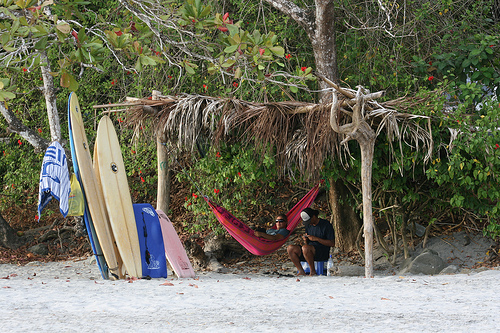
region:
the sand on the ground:
[0, 230, 499, 330]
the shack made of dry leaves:
[91, 73, 461, 277]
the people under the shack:
[252, 207, 336, 274]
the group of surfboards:
[67, 90, 143, 279]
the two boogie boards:
[131, 203, 195, 278]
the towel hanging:
[38, 141, 69, 216]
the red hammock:
[201, 176, 323, 256]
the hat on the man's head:
[300, 206, 316, 223]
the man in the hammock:
[251, 212, 289, 242]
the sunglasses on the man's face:
[274, 217, 285, 224]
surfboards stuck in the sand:
[60, 84, 144, 287]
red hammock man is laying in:
[191, 179, 322, 264]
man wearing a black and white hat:
[285, 208, 332, 273]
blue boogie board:
[135, 202, 168, 277]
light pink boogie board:
[157, 205, 196, 279]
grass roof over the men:
[111, 77, 417, 179]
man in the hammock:
[247, 211, 287, 241]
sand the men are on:
[5, 254, 493, 331]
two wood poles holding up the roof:
[140, 116, 382, 281]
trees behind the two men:
[2, 4, 496, 236]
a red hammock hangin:
[178, 81, 465, 330]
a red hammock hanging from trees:
[172, 135, 379, 282]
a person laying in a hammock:
[204, 121, 349, 276]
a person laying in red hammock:
[167, 134, 439, 330]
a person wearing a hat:
[289, 177, 361, 311]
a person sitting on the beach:
[273, 184, 371, 329]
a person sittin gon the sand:
[269, 186, 349, 301]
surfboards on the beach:
[22, 96, 193, 327]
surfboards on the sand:
[14, 60, 315, 327]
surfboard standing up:
[52, 86, 208, 262]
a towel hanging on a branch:
[36, 144, 68, 222]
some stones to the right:
[409, 250, 474, 275]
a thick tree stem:
[309, 33, 337, 90]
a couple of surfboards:
[67, 95, 145, 278]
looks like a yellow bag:
[69, 179, 83, 212]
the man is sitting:
[288, 210, 334, 274]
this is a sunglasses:
[275, 215, 282, 222]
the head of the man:
[302, 207, 318, 222]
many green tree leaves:
[39, 9, 294, 82]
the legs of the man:
[289, 245, 318, 276]